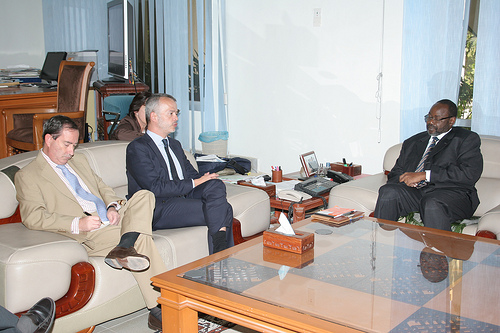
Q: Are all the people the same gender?
A: No, they are both male and female.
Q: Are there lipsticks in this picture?
A: No, there are no lipsticks.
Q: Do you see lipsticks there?
A: No, there are no lipsticks.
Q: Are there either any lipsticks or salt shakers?
A: No, there are no lipsticks or salt shakers.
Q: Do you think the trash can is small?
A: Yes, the trash can is small.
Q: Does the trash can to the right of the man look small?
A: Yes, the trashcan is small.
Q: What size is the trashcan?
A: The trashcan is small.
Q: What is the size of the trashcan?
A: The trashcan is small.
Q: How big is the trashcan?
A: The trashcan is small.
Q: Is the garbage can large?
A: No, the garbage can is small.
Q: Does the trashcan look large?
A: No, the trashcan is small.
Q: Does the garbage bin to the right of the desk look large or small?
A: The trashcan is small.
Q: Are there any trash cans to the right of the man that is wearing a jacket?
A: Yes, there is a trash can to the right of the man.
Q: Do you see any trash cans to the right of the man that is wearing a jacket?
A: Yes, there is a trash can to the right of the man.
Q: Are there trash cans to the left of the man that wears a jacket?
A: No, the trash can is to the right of the man.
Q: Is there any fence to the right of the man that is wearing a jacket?
A: No, there is a trash can to the right of the man.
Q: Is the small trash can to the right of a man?
A: Yes, the garbage can is to the right of a man.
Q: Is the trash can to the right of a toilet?
A: No, the trash can is to the right of a man.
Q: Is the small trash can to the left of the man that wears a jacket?
A: No, the garbage can is to the right of the man.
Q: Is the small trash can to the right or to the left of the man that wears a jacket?
A: The garbage can is to the right of the man.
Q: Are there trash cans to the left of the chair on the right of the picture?
A: Yes, there is a trash can to the left of the chair.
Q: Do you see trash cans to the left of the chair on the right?
A: Yes, there is a trash can to the left of the chair.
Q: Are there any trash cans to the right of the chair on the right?
A: No, the trash can is to the left of the chair.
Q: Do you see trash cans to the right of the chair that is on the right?
A: No, the trash can is to the left of the chair.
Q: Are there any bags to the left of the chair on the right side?
A: No, there is a trash can to the left of the chair.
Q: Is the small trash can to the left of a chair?
A: Yes, the trash bin is to the left of a chair.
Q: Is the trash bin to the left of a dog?
A: No, the trash bin is to the left of a chair.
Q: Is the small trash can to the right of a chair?
A: No, the garbage can is to the left of a chair.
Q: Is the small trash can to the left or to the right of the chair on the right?
A: The garbage can is to the left of the chair.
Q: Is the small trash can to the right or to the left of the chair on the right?
A: The garbage can is to the left of the chair.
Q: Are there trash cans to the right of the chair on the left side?
A: Yes, there is a trash can to the right of the chair.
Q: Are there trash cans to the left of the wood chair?
A: No, the trash can is to the right of the chair.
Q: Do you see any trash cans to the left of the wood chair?
A: No, the trash can is to the right of the chair.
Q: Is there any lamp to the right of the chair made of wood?
A: No, there is a trash can to the right of the chair.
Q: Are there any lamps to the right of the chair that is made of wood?
A: No, there is a trash can to the right of the chair.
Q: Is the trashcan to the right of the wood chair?
A: Yes, the trashcan is to the right of the chair.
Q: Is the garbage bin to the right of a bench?
A: No, the garbage bin is to the right of the chair.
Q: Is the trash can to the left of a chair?
A: No, the trash can is to the right of a chair.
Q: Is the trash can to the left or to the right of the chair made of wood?
A: The trash can is to the right of the chair.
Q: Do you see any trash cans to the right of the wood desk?
A: Yes, there is a trash can to the right of the desk.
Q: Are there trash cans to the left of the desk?
A: No, the trash can is to the right of the desk.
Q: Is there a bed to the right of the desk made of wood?
A: No, there is a trash can to the right of the desk.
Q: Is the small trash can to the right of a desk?
A: Yes, the trash bin is to the right of a desk.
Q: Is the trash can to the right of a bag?
A: No, the trash can is to the right of a desk.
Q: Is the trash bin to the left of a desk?
A: No, the trash bin is to the right of a desk.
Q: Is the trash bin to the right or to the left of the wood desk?
A: The trash bin is to the right of the desk.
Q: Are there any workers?
A: No, there are no workers.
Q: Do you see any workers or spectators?
A: No, there are no workers or spectators.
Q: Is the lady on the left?
A: Yes, the lady is on the left of the image.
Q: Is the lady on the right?
A: No, the lady is on the left of the image.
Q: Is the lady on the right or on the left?
A: The lady is on the left of the image.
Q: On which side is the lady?
A: The lady is on the left of the image.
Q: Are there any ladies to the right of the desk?
A: Yes, there is a lady to the right of the desk.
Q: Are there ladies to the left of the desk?
A: No, the lady is to the right of the desk.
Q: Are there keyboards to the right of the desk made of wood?
A: No, there is a lady to the right of the desk.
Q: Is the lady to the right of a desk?
A: Yes, the lady is to the right of a desk.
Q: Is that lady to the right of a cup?
A: No, the lady is to the right of a desk.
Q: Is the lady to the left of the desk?
A: No, the lady is to the right of the desk.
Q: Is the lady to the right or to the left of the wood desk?
A: The lady is to the right of the desk.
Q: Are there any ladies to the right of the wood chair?
A: Yes, there is a lady to the right of the chair.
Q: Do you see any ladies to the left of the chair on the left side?
A: No, the lady is to the right of the chair.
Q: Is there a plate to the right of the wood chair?
A: No, there is a lady to the right of the chair.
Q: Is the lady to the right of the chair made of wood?
A: Yes, the lady is to the right of the chair.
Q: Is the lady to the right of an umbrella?
A: No, the lady is to the right of the chair.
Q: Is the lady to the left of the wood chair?
A: No, the lady is to the right of the chair.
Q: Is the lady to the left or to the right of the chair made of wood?
A: The lady is to the right of the chair.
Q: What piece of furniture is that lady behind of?
A: The lady is behind the couch.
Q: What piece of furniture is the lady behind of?
A: The lady is behind the couch.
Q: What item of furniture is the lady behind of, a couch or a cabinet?
A: The lady is behind a couch.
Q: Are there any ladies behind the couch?
A: Yes, there is a lady behind the couch.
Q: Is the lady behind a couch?
A: Yes, the lady is behind a couch.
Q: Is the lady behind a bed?
A: No, the lady is behind a couch.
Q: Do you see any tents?
A: No, there are no tents.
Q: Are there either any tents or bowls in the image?
A: No, there are no tents or bowls.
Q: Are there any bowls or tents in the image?
A: No, there are no tents or bowls.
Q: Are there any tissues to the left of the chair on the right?
A: Yes, there is a tissue to the left of the chair.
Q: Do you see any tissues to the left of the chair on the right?
A: Yes, there is a tissue to the left of the chair.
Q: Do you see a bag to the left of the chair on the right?
A: No, there is a tissue to the left of the chair.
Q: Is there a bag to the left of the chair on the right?
A: No, there is a tissue to the left of the chair.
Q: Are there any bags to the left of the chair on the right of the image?
A: No, there is a tissue to the left of the chair.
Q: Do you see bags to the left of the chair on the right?
A: No, there is a tissue to the left of the chair.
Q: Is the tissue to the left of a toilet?
A: No, the tissue is to the left of the chair.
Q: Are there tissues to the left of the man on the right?
A: Yes, there is a tissue to the left of the man.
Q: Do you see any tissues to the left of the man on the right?
A: Yes, there is a tissue to the left of the man.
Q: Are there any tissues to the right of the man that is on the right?
A: No, the tissue is to the left of the man.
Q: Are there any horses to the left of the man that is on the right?
A: No, there is a tissue to the left of the man.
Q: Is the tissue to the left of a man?
A: Yes, the tissue is to the left of a man.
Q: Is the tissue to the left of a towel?
A: No, the tissue is to the left of a man.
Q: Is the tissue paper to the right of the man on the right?
A: No, the tissue paper is to the left of the man.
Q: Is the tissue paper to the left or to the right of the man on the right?
A: The tissue paper is to the left of the man.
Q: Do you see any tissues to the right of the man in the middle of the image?
A: Yes, there is a tissue to the right of the man.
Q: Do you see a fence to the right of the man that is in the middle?
A: No, there is a tissue to the right of the man.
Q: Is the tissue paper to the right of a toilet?
A: No, the tissue paper is to the right of the man.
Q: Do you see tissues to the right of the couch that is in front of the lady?
A: Yes, there is a tissue to the right of the couch.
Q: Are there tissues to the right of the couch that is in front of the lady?
A: Yes, there is a tissue to the right of the couch.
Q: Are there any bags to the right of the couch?
A: No, there is a tissue to the right of the couch.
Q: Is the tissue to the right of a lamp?
A: No, the tissue is to the right of the couch.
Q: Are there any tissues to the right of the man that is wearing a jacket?
A: Yes, there is a tissue to the right of the man.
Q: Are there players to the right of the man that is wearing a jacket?
A: No, there is a tissue to the right of the man.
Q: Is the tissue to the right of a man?
A: Yes, the tissue is to the right of a man.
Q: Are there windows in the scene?
A: Yes, there is a window.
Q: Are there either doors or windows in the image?
A: Yes, there is a window.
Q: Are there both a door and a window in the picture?
A: No, there is a window but no doors.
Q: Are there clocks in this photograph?
A: No, there are no clocks.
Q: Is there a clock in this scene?
A: No, there are no clocks.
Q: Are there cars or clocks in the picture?
A: No, there are no clocks or cars.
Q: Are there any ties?
A: Yes, there is a tie.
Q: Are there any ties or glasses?
A: Yes, there is a tie.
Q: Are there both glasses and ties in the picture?
A: Yes, there are both a tie and glasses.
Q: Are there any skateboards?
A: No, there are no skateboards.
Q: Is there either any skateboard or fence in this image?
A: No, there are no skateboards or fences.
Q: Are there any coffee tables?
A: Yes, there is a coffee table.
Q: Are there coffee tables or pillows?
A: Yes, there is a coffee table.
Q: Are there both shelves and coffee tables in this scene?
A: No, there is a coffee table but no shelves.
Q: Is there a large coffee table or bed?
A: Yes, there is a large coffee table.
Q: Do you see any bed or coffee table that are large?
A: Yes, the coffee table is large.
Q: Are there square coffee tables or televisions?
A: Yes, there is a square coffee table.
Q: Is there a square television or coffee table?
A: Yes, there is a square coffee table.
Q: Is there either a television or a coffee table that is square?
A: Yes, the coffee table is square.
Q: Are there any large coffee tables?
A: Yes, there is a large coffee table.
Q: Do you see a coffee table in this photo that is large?
A: Yes, there is a coffee table that is large.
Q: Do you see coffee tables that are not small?
A: Yes, there is a large coffee table.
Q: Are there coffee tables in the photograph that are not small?
A: Yes, there is a large coffee table.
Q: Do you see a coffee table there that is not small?
A: Yes, there is a large coffee table.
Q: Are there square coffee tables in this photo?
A: Yes, there is a square coffee table.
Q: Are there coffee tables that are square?
A: Yes, there is a coffee table that is square.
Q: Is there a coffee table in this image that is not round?
A: Yes, there is a square coffee table.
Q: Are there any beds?
A: No, there are no beds.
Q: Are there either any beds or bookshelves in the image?
A: No, there are no beds or bookshelves.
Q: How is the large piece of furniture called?
A: The piece of furniture is a coffee table.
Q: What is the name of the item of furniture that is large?
A: The piece of furniture is a coffee table.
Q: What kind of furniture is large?
A: The furniture is a coffee table.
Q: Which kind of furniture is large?
A: The furniture is a coffee table.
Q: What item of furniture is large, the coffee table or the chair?
A: The coffee table is large.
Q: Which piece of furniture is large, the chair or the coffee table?
A: The coffee table is large.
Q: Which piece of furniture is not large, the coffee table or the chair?
A: The chair is not large.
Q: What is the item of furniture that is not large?
A: The piece of furniture is a chair.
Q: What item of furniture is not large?
A: The piece of furniture is a chair.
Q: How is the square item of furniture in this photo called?
A: The piece of furniture is a coffee table.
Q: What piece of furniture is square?
A: The piece of furniture is a coffee table.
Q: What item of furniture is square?
A: The piece of furniture is a coffee table.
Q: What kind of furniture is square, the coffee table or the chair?
A: The coffee table is square.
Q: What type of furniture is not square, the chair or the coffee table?
A: The chair is not square.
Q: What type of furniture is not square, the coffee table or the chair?
A: The chair is not square.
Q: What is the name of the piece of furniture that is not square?
A: The piece of furniture is a chair.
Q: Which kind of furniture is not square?
A: The furniture is a chair.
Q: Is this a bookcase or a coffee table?
A: This is a coffee table.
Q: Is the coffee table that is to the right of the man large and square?
A: Yes, the coffee table is large and square.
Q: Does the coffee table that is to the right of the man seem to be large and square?
A: Yes, the coffee table is large and square.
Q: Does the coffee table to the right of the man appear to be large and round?
A: No, the coffee table is large but square.